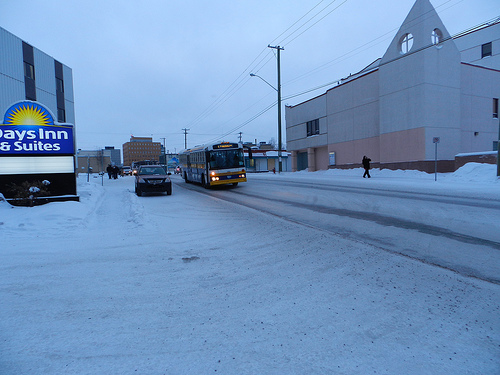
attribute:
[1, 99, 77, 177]
sign — blue, yellow, left. , Days Inn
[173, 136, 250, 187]
bus — yellow, school bus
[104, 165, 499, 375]
road — white, snowy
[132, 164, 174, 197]
suv — maroon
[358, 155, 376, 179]
person — walking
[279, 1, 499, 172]
building — large, white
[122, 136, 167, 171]
building — orange, red, brick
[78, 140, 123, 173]
building — tan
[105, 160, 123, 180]
people — walking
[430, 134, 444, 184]
sign — metal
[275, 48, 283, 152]
pole — wooden, tall, brown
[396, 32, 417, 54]
window — circular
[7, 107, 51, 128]
sun — yellow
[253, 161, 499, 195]
sidewalk — snowy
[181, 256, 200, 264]
mark — black